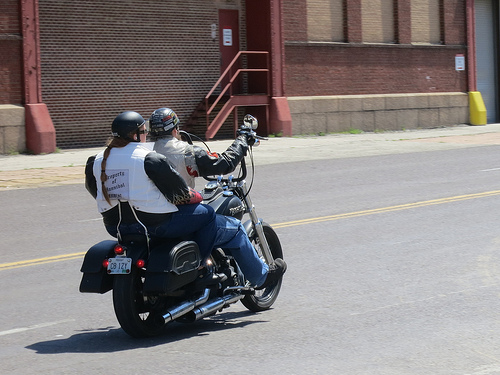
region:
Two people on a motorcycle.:
[36, 30, 385, 365]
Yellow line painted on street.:
[9, 176, 497, 268]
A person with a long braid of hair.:
[76, 103, 196, 233]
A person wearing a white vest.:
[81, 107, 182, 247]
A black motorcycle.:
[73, 179, 299, 332]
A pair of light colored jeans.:
[203, 118, 283, 287]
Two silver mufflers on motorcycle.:
[152, 279, 256, 334]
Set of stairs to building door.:
[178, 43, 278, 136]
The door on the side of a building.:
[211, 5, 247, 82]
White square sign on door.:
[221, 23, 237, 51]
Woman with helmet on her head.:
[95, 101, 147, 147]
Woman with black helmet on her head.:
[92, 105, 147, 150]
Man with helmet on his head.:
[141, 96, 177, 136]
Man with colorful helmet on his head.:
[137, 92, 187, 137]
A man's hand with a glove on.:
[235, 110, 265, 130]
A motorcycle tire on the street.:
[235, 215, 295, 320]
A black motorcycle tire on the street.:
[238, 208, 306, 320]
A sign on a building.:
[445, 47, 468, 77]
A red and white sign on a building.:
[447, 46, 465, 77]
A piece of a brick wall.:
[68, 29, 165, 104]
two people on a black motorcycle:
[46, 83, 320, 330]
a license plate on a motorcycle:
[98, 248, 141, 285]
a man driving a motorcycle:
[147, 98, 309, 318]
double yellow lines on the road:
[0, 186, 497, 279]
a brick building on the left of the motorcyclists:
[0, 0, 475, 140]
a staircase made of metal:
[183, 48, 275, 136]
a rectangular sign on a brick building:
[281, 0, 470, 93]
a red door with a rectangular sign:
[216, 9, 252, 98]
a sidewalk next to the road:
[7, 121, 498, 253]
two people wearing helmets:
[83, 103, 222, 255]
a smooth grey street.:
[351, 155, 467, 320]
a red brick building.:
[272, 0, 497, 159]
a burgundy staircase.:
[182, 43, 282, 142]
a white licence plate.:
[94, 250, 138, 285]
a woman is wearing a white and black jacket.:
[98, 157, 150, 210]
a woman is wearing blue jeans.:
[163, 204, 205, 238]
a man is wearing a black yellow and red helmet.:
[143, 100, 185, 140]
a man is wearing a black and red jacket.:
[180, 104, 265, 189]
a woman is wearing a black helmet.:
[105, 104, 147, 147]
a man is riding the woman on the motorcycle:
[33, 85, 420, 364]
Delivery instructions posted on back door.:
[221, 24, 236, 46]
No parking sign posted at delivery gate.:
[451, 54, 470, 71]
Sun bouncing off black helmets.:
[107, 111, 182, 141]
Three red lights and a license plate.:
[100, 245, 145, 275]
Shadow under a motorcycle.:
[29, 321, 269, 359]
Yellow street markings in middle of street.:
[307, 188, 494, 229]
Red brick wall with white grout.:
[50, 12, 207, 81]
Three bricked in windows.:
[304, 3, 454, 49]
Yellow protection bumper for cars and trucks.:
[466, 88, 488, 125]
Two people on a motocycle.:
[78, 109, 287, 338]